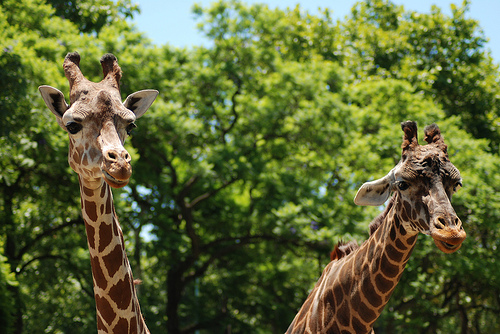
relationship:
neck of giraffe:
[80, 187, 147, 333] [37, 51, 159, 333]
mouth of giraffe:
[101, 169, 130, 186] [37, 51, 159, 333]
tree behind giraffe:
[164, 161, 245, 333] [37, 51, 159, 333]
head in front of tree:
[354, 120, 466, 256] [450, 281, 474, 330]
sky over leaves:
[111, 1, 216, 53] [342, 1, 496, 156]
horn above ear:
[63, 49, 85, 87] [40, 84, 68, 121]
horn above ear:
[401, 120, 419, 150] [354, 174, 396, 207]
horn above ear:
[100, 50, 124, 87] [122, 88, 159, 118]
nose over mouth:
[435, 214, 462, 229] [441, 239, 462, 251]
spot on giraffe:
[99, 221, 113, 256] [37, 51, 159, 333]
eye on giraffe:
[66, 122, 84, 134] [37, 51, 159, 333]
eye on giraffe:
[396, 179, 411, 192] [284, 120, 467, 334]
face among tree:
[354, 120, 466, 256] [3, 174, 27, 334]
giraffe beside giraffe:
[284, 120, 467, 334] [37, 51, 159, 333]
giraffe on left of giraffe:
[37, 51, 159, 333] [284, 120, 467, 334]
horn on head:
[424, 119, 446, 150] [354, 120, 466, 256]